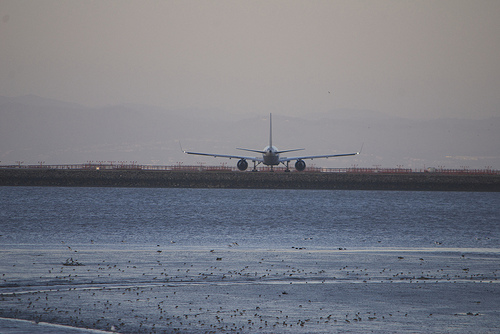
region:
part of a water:
[343, 213, 378, 252]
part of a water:
[262, 216, 299, 270]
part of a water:
[333, 203, 408, 265]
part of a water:
[390, 197, 420, 228]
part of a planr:
[275, 122, 316, 207]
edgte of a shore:
[356, 225, 385, 255]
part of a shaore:
[392, 166, 427, 225]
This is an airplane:
[178, 108, 377, 199]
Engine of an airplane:
[293, 155, 306, 184]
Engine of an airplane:
[236, 154, 249, 173]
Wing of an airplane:
[276, 149, 367, 169]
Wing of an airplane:
[187, 147, 261, 173]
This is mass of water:
[108, 208, 179, 248]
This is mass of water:
[247, 202, 362, 279]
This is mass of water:
[349, 182, 486, 272]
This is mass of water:
[29, 192, 148, 260]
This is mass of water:
[63, 187, 498, 247]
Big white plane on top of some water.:
[186, 122, 373, 186]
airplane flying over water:
[182, 108, 362, 195]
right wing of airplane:
[275, 151, 369, 166]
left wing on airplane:
[177, 148, 255, 168]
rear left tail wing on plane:
[231, 146, 267, 156]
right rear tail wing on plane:
[270, 146, 302, 155]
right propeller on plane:
[297, 160, 308, 175]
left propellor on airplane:
[231, 157, 252, 171]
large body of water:
[141, 192, 233, 232]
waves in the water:
[430, 207, 458, 226]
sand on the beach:
[356, 285, 418, 311]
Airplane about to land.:
[175, 100, 367, 177]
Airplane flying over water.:
[0, 100, 495, 320]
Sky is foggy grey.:
[0, 0, 495, 135]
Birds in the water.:
[5, 230, 495, 330]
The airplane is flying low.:
[180, 106, 360, 176]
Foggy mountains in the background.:
[6, 81, 491, 136]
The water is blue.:
[5, 190, 495, 235]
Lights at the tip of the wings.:
[177, 146, 372, 161]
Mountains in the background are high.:
[5, 86, 158, 156]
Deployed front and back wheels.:
[246, 162, 293, 177]